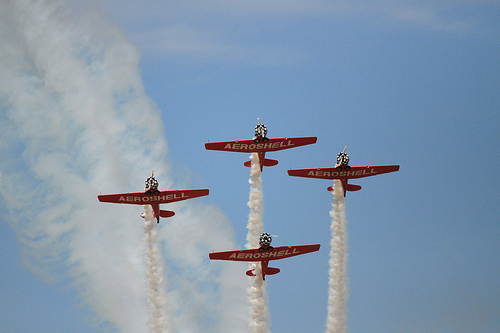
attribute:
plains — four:
[89, 103, 434, 314]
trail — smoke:
[321, 174, 360, 323]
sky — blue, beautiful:
[7, 7, 469, 323]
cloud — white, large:
[18, 27, 215, 325]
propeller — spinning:
[251, 109, 271, 139]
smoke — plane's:
[236, 143, 298, 323]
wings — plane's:
[203, 133, 331, 169]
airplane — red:
[198, 221, 339, 294]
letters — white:
[304, 168, 384, 183]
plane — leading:
[174, 100, 347, 196]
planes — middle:
[106, 139, 402, 234]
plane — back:
[206, 213, 355, 281]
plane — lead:
[204, 123, 340, 225]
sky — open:
[346, 49, 495, 316]